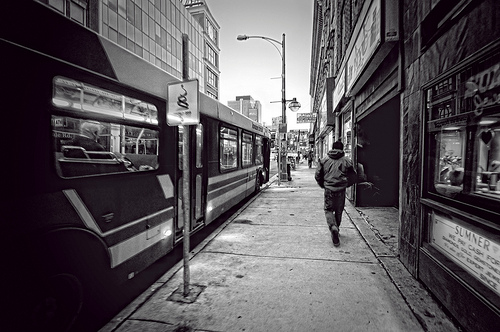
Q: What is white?
A: The sign.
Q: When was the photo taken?
A: Day time.